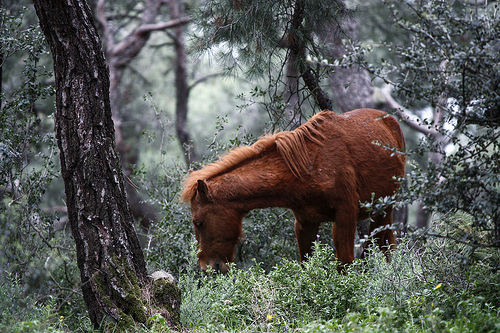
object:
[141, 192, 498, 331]
vegetation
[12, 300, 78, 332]
dandelion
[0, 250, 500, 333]
grasses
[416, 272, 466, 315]
weeds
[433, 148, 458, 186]
ground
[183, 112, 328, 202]
hair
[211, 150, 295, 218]
neck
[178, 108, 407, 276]
horse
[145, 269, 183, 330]
stone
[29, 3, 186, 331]
dark tree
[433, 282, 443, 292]
dandy lion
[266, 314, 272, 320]
dandy lion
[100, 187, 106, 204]
white spot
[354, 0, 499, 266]
tree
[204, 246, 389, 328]
plant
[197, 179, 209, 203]
ear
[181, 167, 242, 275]
head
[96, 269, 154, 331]
moss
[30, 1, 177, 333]
tree trunk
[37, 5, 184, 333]
bark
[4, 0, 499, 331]
background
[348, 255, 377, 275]
part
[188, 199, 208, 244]
part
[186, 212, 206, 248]
part